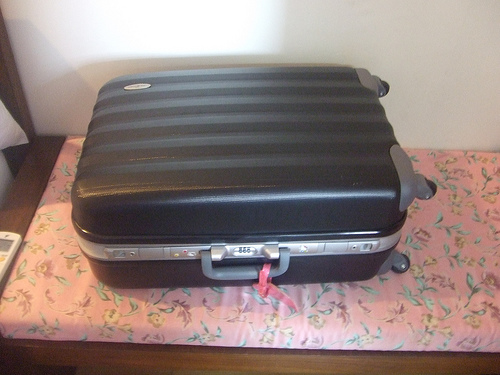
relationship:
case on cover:
[70, 66, 437, 290] [0, 134, 499, 353]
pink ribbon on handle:
[252, 263, 300, 313] [198, 244, 290, 283]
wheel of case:
[381, 79, 390, 97] [70, 66, 437, 290]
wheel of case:
[416, 177, 438, 200] [70, 66, 437, 290]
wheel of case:
[392, 253, 410, 274] [70, 66, 437, 290]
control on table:
[0, 230, 22, 280] [3, 132, 498, 372]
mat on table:
[56, 132, 469, 344] [22, 341, 384, 368]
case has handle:
[70, 66, 437, 290] [198, 244, 290, 283]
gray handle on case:
[199, 245, 291, 282] [70, 66, 437, 290]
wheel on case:
[392, 253, 410, 274] [70, 66, 437, 290]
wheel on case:
[413, 170, 438, 200] [70, 66, 437, 290]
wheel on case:
[381, 79, 390, 97] [70, 66, 437, 290]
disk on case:
[124, 83, 152, 91] [70, 66, 437, 290]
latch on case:
[344, 239, 379, 254] [70, 66, 437, 290]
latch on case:
[103, 246, 139, 262] [70, 66, 437, 290]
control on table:
[0, 226, 22, 294] [3, 132, 498, 372]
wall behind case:
[2, 3, 498, 152] [70, 66, 437, 290]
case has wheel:
[70, 66, 437, 290] [381, 79, 390, 97]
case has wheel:
[70, 66, 437, 290] [417, 177, 438, 194]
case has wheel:
[70, 66, 437, 290] [393, 253, 409, 275]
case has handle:
[70, 66, 437, 290] [201, 250, 291, 282]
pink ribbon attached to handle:
[253, 265, 298, 312] [201, 250, 291, 282]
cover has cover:
[0, 134, 499, 353] [3, 130, 499, 354]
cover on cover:
[0, 134, 499, 353] [3, 130, 499, 354]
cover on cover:
[0, 134, 499, 353] [0, 134, 499, 353]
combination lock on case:
[225, 243, 262, 263] [71, 53, 438, 292]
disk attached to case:
[122, 79, 152, 91] [71, 53, 438, 292]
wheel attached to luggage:
[375, 74, 389, 97] [101, 45, 403, 256]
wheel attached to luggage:
[416, 177, 438, 200] [101, 45, 403, 256]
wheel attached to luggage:
[395, 253, 413, 272] [101, 45, 403, 256]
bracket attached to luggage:
[353, 63, 391, 94] [101, 45, 403, 256]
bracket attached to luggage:
[389, 144, 439, 210] [101, 45, 403, 256]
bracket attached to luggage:
[377, 249, 411, 275] [101, 45, 403, 256]